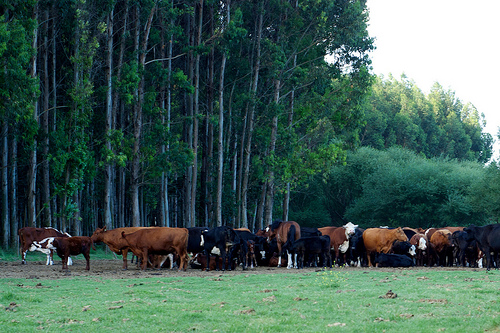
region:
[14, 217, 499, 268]
herd of cows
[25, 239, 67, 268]
white calf with brown spots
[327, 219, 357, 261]
brown cow with white face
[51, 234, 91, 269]
dark brown calf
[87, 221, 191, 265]
two brown cows side by side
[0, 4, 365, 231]
tall trees behind the herd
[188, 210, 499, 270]
black cows among the brown cows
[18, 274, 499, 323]
grass pasture in front of herd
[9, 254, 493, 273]
dirt patch the herd is on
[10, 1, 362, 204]
leaves on the tall trees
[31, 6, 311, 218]
A grouping of tall and narrow trees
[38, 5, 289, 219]
A grouping of narrow trees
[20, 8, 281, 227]
A grouping of several tall trees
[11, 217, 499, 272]
A grouping of several cows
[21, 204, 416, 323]
Cows grazing on a pasture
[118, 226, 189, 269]
A brown cow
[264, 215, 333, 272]
A brown horse among cows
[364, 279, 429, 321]
Cow manure on a green pasture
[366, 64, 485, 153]
The tops of green trees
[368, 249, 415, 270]
A black cow laying down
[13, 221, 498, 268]
A herd of cows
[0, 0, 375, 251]
Trees with leaves on them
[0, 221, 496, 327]
Cows grazing on grass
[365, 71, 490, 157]
Sun shining on trees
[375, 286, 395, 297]
Excrement of cow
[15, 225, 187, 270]
Brown and white cows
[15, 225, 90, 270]
Brown and white cows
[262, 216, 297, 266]
A horse amongst the cows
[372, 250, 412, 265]
Cow lying on ground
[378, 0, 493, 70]
Clear, sunny skies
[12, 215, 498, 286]
a bunch of cows on the forest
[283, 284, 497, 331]
cows stepping at the green grass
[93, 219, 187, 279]
some cows are color brown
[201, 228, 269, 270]
some cows are color black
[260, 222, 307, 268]
one horse at the middle of the cows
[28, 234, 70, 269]
the cow's head is color white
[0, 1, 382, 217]
tall trees at the left side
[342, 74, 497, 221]
fluffy trees at the right side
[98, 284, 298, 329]
some dirt at the ground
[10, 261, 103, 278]
the cow standing at the dried corner of the gound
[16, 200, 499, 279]
a herd of cows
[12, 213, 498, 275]
cows on the grass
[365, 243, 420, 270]
black cow laying on the grass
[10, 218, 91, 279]
brown and white cow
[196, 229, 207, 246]
white spot on the black cow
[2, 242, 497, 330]
green grass on the ground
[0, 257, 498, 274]
dirt path on the grass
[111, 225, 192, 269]
side profile of a cow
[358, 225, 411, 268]
light brown cow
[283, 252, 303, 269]
legs are white